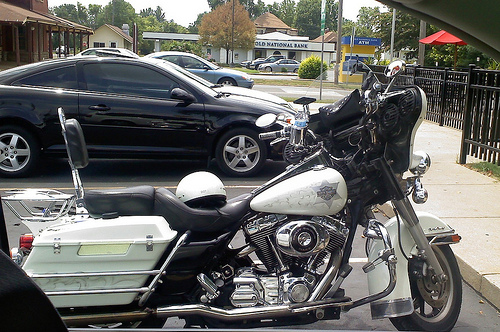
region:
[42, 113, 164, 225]
Black seat on a motorcycle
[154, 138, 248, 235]
White helmet on a motorcycle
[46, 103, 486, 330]
Black and white motorcycle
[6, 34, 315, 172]
Black car in a parking lot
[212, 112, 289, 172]
Wheel on a car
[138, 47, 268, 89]
Silver car in a parking lot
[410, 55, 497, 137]
Black fence by a sidewalk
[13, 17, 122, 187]
Brick building by a parking lot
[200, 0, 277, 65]
Tree with brown leaves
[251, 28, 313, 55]
Writing on a building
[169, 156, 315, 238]
white helmet on motorbike seat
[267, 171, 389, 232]
six point gray star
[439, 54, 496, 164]
4 feet iron black gate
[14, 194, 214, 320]
white storage case for motorbike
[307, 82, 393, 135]
black bag storage space for bike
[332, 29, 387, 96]
yellow and blue ATM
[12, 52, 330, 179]
shiny 2 door black car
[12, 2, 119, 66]
old brown wood porch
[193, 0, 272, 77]
brown and yellow tree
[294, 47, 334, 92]
green bush near sidewalk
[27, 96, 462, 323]
police motorcycle in a car park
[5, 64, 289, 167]
black coupe in a car park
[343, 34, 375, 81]
ATM machine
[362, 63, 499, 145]
metal railings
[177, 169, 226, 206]
white helmet on motorcycle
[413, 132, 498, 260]
concrete sidewalk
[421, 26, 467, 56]
red beach umbrella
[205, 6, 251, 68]
a tree in front of white building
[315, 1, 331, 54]
green sign post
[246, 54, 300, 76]
cars parked in front of white building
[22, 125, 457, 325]
this is a motorbike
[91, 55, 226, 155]
this is a car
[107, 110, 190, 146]
the car is black in color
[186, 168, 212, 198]
this is a helmet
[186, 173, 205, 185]
the helmet is white in color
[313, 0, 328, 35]
this is a signpost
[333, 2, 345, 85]
this is a pole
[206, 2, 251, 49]
this is a tree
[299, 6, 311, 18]
the tree has green leaves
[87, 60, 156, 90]
the window are closed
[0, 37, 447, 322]
a white motorcycle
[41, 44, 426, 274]
a white helmet sitting on a motorcycle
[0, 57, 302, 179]
a black car parked in a parking space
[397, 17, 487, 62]
a red umbrella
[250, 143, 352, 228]
gas tank on a motorcycle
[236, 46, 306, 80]
several cars parked in a lot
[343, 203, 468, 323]
front wheel of a motorcycle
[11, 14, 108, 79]
a building with a long porch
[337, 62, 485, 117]
a black iron fence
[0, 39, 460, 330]
a motorcycle parked in a parking space